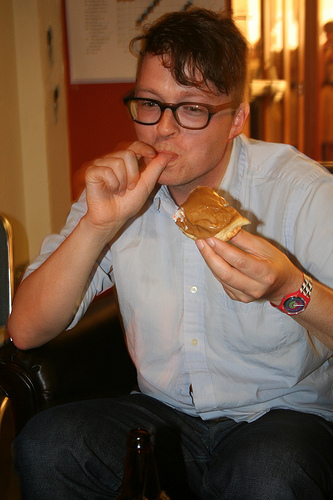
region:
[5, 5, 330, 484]
boy wearing blue shirt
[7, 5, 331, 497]
boy holding doughnut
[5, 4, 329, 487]
boy wearing red, white and black watch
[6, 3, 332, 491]
boy wearing black eyeglasses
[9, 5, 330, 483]
boy with brown hair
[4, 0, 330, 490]
boy with finger in mouth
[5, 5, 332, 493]
boy licking finger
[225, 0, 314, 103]
lights lit behind boy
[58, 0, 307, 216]
orange wall next to lights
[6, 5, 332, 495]
boy wearing blue jeans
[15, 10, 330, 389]
Man eating a sandwich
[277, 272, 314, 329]
Red watch with black and white strap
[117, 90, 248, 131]
One pair of eye glasses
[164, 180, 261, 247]
Half eaten sandwich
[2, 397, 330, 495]
Man's dark blue jeans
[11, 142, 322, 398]
Man's light blue casual shirt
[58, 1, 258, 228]
Man licking his fingers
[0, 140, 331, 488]
Man's light blue and dark blue outfit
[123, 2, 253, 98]
Man's messy hair style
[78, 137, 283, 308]
Man's hands that he's using for eating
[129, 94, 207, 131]
a pair of glasses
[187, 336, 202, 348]
a white button on the mans shirt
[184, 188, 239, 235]
a caramel pastry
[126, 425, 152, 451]
top of a bottle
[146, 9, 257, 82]
the man has black hair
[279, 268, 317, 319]
a red watch on the mans wrist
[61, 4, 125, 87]
a white board in the background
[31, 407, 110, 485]
the man is wearing blue jeans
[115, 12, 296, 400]
man enjoying a desert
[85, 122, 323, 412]
the man is wearing a blue button up shirt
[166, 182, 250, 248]
brown bread roll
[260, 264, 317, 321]
multicolored watch on left arm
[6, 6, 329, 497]
man wearing light shirt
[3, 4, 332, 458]
man wearing dark glasses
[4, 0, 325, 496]
man wearing dark jeans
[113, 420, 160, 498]
reddish bottle top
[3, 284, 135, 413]
black leather chair arm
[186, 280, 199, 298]
pearl finish shirt button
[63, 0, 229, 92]
black and white crossword on wall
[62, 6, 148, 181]
red wall in background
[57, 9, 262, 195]
a man sucking on his thumb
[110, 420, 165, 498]
top of a brown glass bottle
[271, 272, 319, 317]
a multi colored watch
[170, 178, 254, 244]
piece of bread with peanut butter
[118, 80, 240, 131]
black framed glasses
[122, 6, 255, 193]
man with his hair shaved on the sides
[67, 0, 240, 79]
white board with a chart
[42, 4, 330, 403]
man with a blue button up shirt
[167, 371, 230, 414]
a missing button on a shirt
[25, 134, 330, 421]
a light blue button up shirt